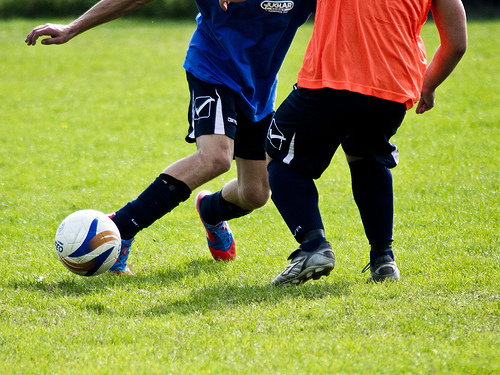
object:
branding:
[190, 94, 214, 121]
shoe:
[196, 191, 235, 262]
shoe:
[97, 211, 139, 278]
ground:
[0, 16, 498, 373]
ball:
[55, 208, 125, 277]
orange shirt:
[297, 0, 426, 107]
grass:
[0, 0, 499, 373]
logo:
[260, 0, 295, 17]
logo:
[266, 113, 286, 152]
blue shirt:
[184, 2, 313, 121]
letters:
[261, 0, 290, 15]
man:
[258, 0, 471, 285]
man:
[21, 0, 317, 275]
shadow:
[0, 223, 499, 375]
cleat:
[289, 261, 337, 283]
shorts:
[184, 83, 275, 161]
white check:
[269, 128, 285, 141]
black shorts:
[267, 83, 407, 175]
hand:
[25, 23, 72, 47]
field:
[2, 0, 499, 375]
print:
[187, 95, 212, 123]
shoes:
[266, 242, 337, 289]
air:
[1, 2, 177, 83]